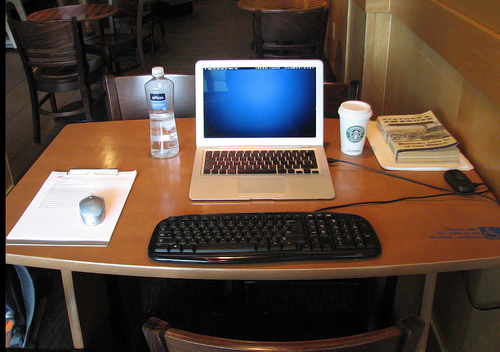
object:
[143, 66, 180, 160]
bottle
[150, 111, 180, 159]
water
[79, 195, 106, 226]
mouse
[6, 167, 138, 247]
clipboard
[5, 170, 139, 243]
paper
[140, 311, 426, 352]
chair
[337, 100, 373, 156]
cup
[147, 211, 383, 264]
keyboard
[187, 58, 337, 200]
laptop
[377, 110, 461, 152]
cover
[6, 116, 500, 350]
table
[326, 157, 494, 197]
wires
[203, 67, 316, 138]
screen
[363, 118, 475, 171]
papers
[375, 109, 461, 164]
book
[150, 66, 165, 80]
cap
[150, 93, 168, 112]
lable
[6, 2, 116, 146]
chair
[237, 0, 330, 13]
table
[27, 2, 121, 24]
table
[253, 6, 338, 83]
chair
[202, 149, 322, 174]
keyboard